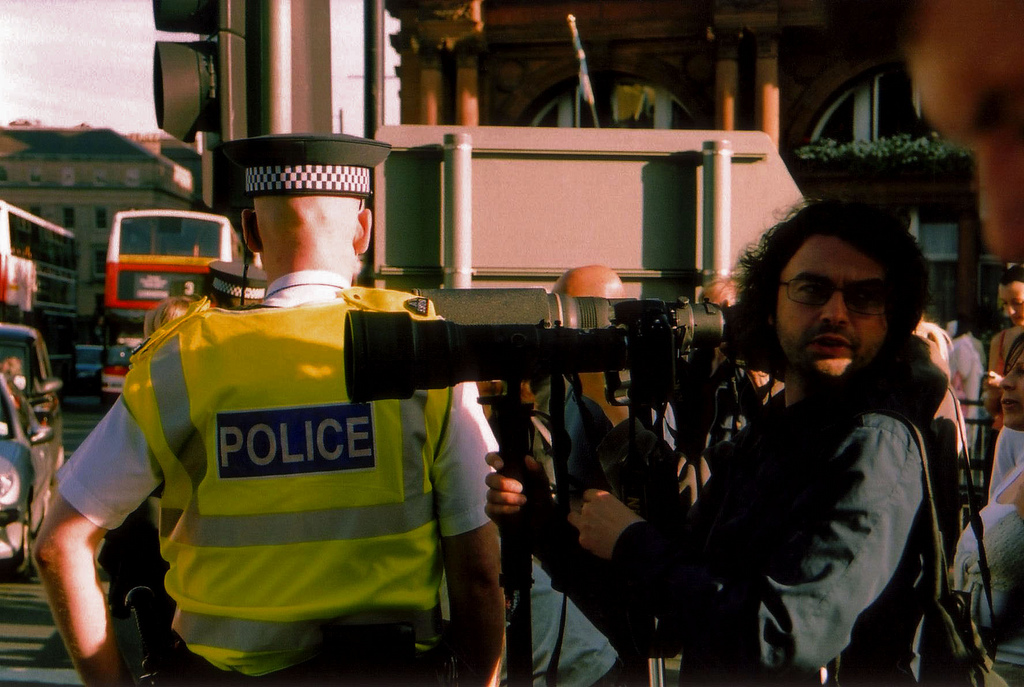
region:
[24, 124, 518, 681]
man wearing police vest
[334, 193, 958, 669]
man holding camera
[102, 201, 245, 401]
Bus with number 3 in front of it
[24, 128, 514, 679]
man wearing a hat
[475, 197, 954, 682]
man wearing black jacket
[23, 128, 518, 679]
man wearing a white shirt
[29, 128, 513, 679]
Police vest is yellow and black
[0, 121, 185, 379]
building with lots of window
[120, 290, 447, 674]
yellow police safety vest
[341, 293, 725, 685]
camera with large lens on monopod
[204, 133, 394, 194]
cop's hat with checkerboard pattern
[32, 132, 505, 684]
police officer wearing a yellow vest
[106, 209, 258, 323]
yellow and red city bus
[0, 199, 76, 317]
yellow and red city bus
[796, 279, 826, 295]
a man's right eye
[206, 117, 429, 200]
Man wearing black hat.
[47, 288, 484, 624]
Man wearing white shirt under vest.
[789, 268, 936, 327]
Glasses on person's face.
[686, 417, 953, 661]
Person wearing dark shirt.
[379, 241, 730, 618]
Person holding camera in hand.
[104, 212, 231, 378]
Double decker bus in distance.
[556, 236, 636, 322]
Person has bald head.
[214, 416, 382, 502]
Police written on back of vest.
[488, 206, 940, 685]
A cameraman on a London street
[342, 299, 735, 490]
Camera with a telephotplens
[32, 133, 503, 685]
A police officer on a London street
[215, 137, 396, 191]
A peculier hat the policeman is wearing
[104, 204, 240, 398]
A red double-decker bus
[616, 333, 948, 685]
Hoodede jacket of the photographer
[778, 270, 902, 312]
The spectacles worn by the photographer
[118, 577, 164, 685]
Handle of the baton the policeman is carrying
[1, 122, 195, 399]
Buildings at the far end of the road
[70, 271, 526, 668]
a yellow police vest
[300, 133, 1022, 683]
man holding a camera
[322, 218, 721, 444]
a long camera lense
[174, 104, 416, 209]
man wearing a hat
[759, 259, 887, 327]
a pair of glasses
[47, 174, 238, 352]
bus in the background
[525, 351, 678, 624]
pole on the camera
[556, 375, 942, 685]
man wearing a black top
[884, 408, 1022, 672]
bag on mans shoulder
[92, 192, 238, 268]
white top of bus